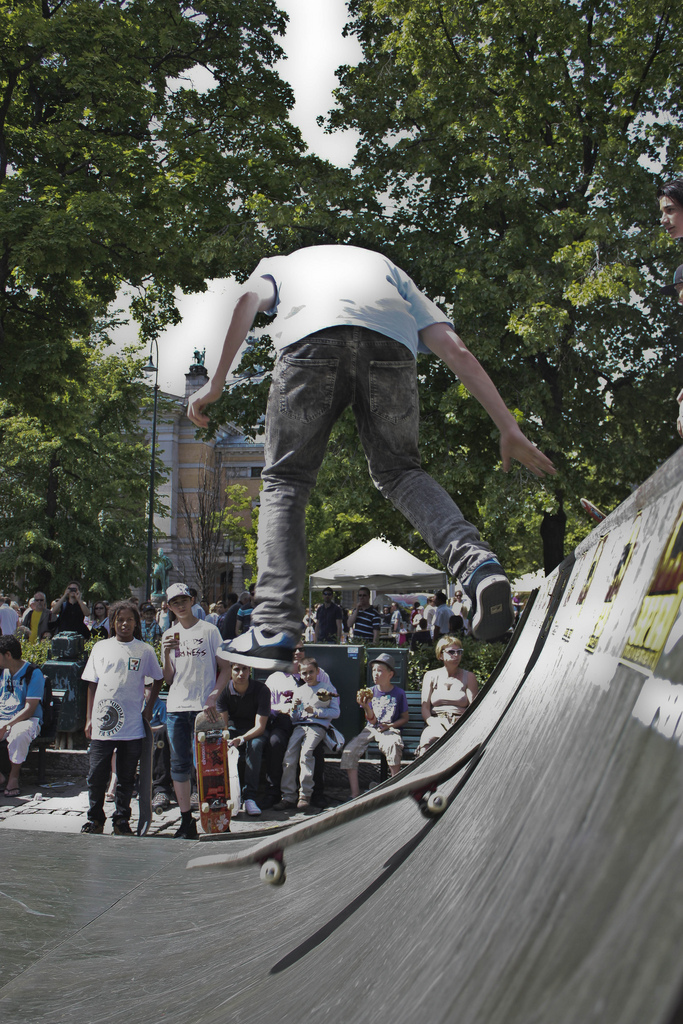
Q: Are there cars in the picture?
A: No, there are no cars.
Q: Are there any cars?
A: No, there are no cars.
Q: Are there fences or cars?
A: No, there are no cars or fences.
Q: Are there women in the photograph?
A: Yes, there is a woman.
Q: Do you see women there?
A: Yes, there is a woman.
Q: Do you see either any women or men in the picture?
A: Yes, there is a woman.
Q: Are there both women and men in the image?
A: Yes, there are both a woman and a man.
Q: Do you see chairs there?
A: No, there are no chairs.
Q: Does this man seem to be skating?
A: Yes, the man is skating.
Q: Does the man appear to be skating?
A: Yes, the man is skating.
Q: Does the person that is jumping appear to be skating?
A: Yes, the man is skating.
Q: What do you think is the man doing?
A: The man is skating.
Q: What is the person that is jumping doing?
A: The man is skating.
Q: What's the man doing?
A: The man is skating.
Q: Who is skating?
A: The man is skating.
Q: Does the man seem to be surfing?
A: No, the man is skating.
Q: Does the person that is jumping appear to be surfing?
A: No, the man is skating.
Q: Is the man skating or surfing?
A: The man is skating.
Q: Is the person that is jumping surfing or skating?
A: The man is skating.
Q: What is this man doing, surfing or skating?
A: The man is skating.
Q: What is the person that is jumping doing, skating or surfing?
A: The man is skating.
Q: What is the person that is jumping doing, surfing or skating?
A: The man is skating.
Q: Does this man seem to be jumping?
A: Yes, the man is jumping.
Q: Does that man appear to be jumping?
A: Yes, the man is jumping.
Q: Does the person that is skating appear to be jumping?
A: Yes, the man is jumping.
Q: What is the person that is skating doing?
A: The man is jumping.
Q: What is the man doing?
A: The man is jumping.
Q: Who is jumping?
A: The man is jumping.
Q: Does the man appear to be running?
A: No, the man is jumping.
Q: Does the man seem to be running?
A: No, the man is jumping.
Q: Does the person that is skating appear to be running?
A: No, the man is jumping.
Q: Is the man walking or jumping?
A: The man is jumping.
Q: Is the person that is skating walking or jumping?
A: The man is jumping.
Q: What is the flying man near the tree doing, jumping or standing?
A: The man is jumping.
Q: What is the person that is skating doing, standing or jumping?
A: The man is jumping.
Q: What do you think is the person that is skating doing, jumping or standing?
A: The man is jumping.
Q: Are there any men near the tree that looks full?
A: Yes, there is a man near the tree.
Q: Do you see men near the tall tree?
A: Yes, there is a man near the tree.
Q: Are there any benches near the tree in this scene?
A: No, there is a man near the tree.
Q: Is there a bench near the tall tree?
A: No, there is a man near the tree.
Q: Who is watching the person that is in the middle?
A: The people are watching the man.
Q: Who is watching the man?
A: The people are watching the man.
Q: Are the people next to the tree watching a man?
A: Yes, the people are watching a man.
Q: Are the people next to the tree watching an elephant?
A: No, the people are watching a man.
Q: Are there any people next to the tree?
A: Yes, there are people next to the tree.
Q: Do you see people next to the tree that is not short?
A: Yes, there are people next to the tree.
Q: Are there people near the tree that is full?
A: Yes, there are people near the tree.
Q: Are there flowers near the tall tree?
A: No, there are people near the tree.